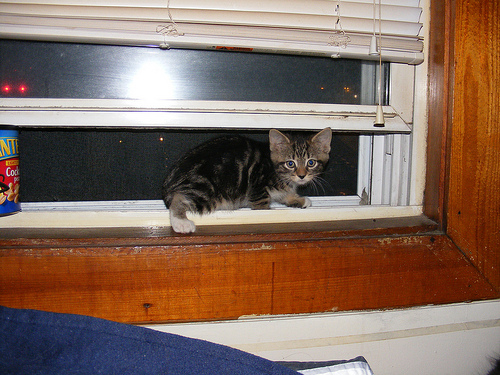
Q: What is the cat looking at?
A: Camera.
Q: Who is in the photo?
A: Nobody.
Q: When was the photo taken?
A: Night time.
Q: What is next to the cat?
A: A can.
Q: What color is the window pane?
A: White.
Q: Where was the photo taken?
A: Next to a window.